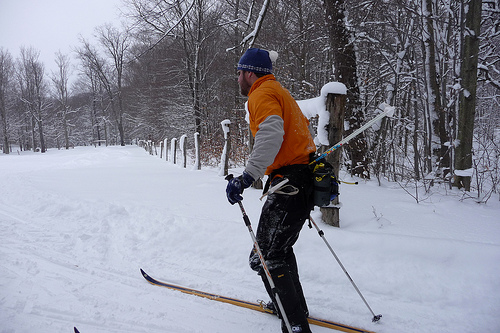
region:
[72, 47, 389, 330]
a cross country skier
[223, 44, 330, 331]
a man skiing cross country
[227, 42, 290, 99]
a man with a sock hat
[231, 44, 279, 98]
a man with a blue sock hat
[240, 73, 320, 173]
a man in an orange sweater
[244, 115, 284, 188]
gray sleeve of a man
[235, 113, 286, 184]
gray sleeve of a skiier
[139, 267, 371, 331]
a long cross country ski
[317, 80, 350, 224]
snow capped fence post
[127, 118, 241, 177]
a fence in the snow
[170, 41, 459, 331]
man skiing in a orange shirt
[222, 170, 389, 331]
pair of black and white ski poles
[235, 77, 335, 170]
orange collard shirt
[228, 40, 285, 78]
blue and white beanie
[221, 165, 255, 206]
black winter glove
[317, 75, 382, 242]
wooden fence post with snow on top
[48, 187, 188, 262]
white snow with footprints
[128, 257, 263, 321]
white and black ski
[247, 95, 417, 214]
ice pick with white handle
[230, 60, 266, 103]
face of a man with a brown beard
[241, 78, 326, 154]
the shirt is orange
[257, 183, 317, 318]
the pants are black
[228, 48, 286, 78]
the marvin is blue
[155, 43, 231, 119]
the trees have snow on it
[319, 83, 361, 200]
the pole has snow on it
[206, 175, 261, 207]
the gloves are blue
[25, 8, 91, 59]
the sky is cloudless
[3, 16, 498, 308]
the photo was taken during winter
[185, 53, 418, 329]
the guy is skiing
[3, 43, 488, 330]
the photo was taken during the day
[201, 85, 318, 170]
An short sleeved orange Polo shirt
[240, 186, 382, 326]
Two ski poles that help with turns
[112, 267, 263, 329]
Cross country ski tip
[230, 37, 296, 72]
Navy blue ski cap with white stripe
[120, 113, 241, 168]
wooden fence posts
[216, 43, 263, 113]
This male skier has a beard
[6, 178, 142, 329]
Snow disturbed along the ski trail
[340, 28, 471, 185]
The snow sticks on the trees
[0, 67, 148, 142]
A hilltop shows in the distance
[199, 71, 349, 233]
The grey shirt under the orange is long sleeved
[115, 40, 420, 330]
A man on skis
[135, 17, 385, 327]
A man skiing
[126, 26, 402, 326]
A man going skiing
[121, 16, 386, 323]
A man on snow skis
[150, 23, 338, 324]
A skiing man